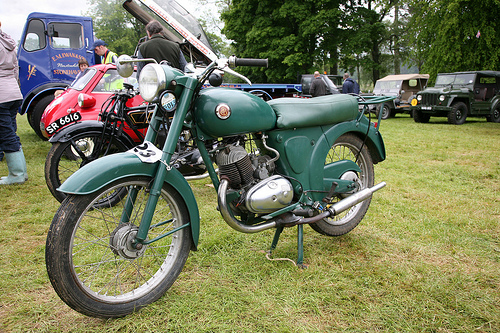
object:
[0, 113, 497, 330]
grass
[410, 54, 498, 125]
cab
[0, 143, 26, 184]
boots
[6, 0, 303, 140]
truck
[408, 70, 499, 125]
jeep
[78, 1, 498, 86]
trees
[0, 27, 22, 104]
coat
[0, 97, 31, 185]
jeans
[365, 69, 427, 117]
jeep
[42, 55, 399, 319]
bike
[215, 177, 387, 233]
chrome muffler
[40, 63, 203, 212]
car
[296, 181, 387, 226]
pipe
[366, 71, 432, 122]
cover